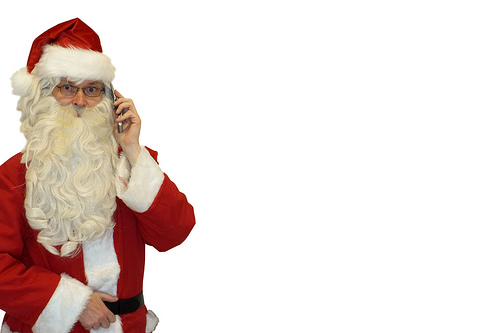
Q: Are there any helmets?
A: No, there are no helmets.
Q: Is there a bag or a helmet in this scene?
A: No, there are no helmets or bags.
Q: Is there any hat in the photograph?
A: Yes, there is a hat.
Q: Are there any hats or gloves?
A: Yes, there is a hat.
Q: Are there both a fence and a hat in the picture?
A: No, there is a hat but no fences.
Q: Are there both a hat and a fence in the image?
A: No, there is a hat but no fences.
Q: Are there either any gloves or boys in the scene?
A: No, there are no boys or gloves.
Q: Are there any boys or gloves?
A: No, there are no boys or gloves.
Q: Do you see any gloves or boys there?
A: No, there are no boys or gloves.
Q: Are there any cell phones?
A: Yes, there is a cell phone.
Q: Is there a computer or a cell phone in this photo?
A: Yes, there is a cell phone.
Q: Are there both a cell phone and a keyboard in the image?
A: No, there is a cell phone but no keyboards.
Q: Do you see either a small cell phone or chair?
A: Yes, there is a small cell phone.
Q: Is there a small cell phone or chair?
A: Yes, there is a small cell phone.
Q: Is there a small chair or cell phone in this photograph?
A: Yes, there is a small cell phone.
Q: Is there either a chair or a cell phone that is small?
A: Yes, the cell phone is small.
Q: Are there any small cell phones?
A: Yes, there is a small cell phone.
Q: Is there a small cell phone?
A: Yes, there is a small cell phone.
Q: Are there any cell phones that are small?
A: Yes, there is a cell phone that is small.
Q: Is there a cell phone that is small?
A: Yes, there is a cell phone that is small.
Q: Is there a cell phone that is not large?
A: Yes, there is a small cell phone.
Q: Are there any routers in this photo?
A: No, there are no routers.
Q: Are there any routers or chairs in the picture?
A: No, there are no routers or chairs.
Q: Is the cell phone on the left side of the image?
A: Yes, the cell phone is on the left of the image.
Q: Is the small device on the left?
A: Yes, the cell phone is on the left of the image.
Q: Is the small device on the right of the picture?
A: No, the cell phone is on the left of the image.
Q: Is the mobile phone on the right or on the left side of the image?
A: The mobile phone is on the left of the image.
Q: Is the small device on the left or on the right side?
A: The mobile phone is on the left of the image.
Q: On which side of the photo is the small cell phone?
A: The mobile phone is on the left of the image.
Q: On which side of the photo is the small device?
A: The mobile phone is on the left of the image.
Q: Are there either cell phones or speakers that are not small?
A: No, there is a cell phone but it is small.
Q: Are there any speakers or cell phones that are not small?
A: No, there is a cell phone but it is small.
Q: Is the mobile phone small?
A: Yes, the mobile phone is small.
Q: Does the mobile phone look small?
A: Yes, the mobile phone is small.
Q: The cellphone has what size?
A: The cellphone is small.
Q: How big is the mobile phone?
A: The mobile phone is small.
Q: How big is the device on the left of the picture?
A: The mobile phone is small.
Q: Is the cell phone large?
A: No, the cell phone is small.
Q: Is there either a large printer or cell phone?
A: No, there is a cell phone but it is small.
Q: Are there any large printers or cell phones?
A: No, there is a cell phone but it is small.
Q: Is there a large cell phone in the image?
A: No, there is a cell phone but it is small.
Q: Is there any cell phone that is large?
A: No, there is a cell phone but it is small.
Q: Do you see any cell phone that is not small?
A: No, there is a cell phone but it is small.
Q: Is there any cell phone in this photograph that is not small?
A: No, there is a cell phone but it is small.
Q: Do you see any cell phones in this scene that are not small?
A: No, there is a cell phone but it is small.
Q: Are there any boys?
A: No, there are no boys.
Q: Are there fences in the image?
A: No, there are no fences.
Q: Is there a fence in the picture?
A: No, there are no fences.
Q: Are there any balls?
A: Yes, there is a ball.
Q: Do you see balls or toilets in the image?
A: Yes, there is a ball.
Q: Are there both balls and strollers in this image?
A: No, there is a ball but no strollers.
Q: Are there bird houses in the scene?
A: No, there are no bird houses.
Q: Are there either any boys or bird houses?
A: No, there are no bird houses or boys.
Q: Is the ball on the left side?
A: Yes, the ball is on the left of the image.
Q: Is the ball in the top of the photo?
A: Yes, the ball is in the top of the image.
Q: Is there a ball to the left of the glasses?
A: Yes, there is a ball to the left of the glasses.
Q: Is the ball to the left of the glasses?
A: Yes, the ball is to the left of the glasses.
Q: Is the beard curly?
A: Yes, the beard is curly.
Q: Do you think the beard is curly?
A: Yes, the beard is curly.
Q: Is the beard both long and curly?
A: Yes, the beard is long and curly.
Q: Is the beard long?
A: Yes, the beard is long.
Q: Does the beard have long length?
A: Yes, the beard is long.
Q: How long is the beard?
A: The beard is long.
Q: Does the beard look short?
A: No, the beard is long.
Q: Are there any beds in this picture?
A: No, there are no beds.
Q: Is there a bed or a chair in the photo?
A: No, there are no beds or chairs.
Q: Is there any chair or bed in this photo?
A: No, there are no beds or chairs.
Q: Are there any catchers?
A: No, there are no catchers.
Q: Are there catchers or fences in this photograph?
A: No, there are no catchers or fences.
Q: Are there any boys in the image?
A: No, there are no boys.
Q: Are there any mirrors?
A: No, there are no mirrors.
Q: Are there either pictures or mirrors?
A: No, there are no mirrors or pictures.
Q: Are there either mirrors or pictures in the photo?
A: No, there are no mirrors or pictures.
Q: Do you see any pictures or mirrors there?
A: No, there are no mirrors or pictures.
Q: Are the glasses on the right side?
A: No, the glasses are on the left of the image.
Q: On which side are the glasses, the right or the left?
A: The glasses are on the left of the image.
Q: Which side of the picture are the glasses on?
A: The glasses are on the left of the image.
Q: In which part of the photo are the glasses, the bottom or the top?
A: The glasses are in the top of the image.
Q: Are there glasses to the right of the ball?
A: Yes, there are glasses to the right of the ball.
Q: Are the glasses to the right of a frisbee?
A: No, the glasses are to the right of a ball.